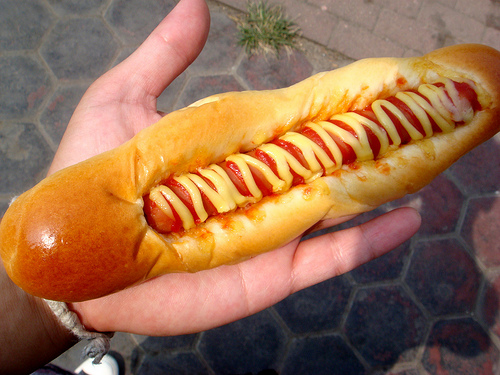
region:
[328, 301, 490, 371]
the shadow is on the ground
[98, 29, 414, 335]
the hand is open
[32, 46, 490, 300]
the bun is big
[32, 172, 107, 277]
the bun is brown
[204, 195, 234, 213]
the mustard is yellow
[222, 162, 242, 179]
the ketchup is red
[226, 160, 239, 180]
the ketchup is on the hotdog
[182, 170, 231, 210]
the mustard is on the hotdog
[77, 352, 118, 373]
the shoe is white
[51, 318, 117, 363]
the bracelet is rope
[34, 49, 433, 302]
a sandwich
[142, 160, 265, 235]
cheese on a hot dog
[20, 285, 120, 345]
person wearing a bracelet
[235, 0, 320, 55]
weed in the sidewalk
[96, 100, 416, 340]
person holding a hot dog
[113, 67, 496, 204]
hotdog baked in a bun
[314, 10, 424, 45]
bricks in the sidewalk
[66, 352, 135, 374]
top of white shoe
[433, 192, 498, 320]
graffiti on the bricks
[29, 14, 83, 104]
bricks are grey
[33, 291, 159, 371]
the bracelet is white yarn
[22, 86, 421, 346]
the sandwich is yellow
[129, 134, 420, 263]
the sandwich is yellow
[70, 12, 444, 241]
the sandwich is yellow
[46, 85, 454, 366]
a sandwich with cheese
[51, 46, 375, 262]
a sandwich with cheese